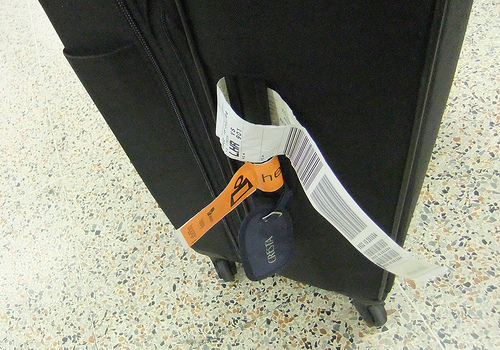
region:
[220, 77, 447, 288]
White tag on luggage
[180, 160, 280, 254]
Yellow tag on luggage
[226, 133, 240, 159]
Black letters on white tag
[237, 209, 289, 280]
Cloth tag on luggage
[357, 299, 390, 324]
Small wheel on luggage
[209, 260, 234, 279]
Small wheel on luggage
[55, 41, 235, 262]
Pocket on side of luggage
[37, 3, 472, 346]
Tall suitcase on floor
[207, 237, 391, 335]
black wheels on the luggage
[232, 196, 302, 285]
travel identification tag attached to the luggage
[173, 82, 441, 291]
travel tags attached to the luggage handle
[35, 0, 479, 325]
rolling black luggage sitting on a floor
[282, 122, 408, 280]
barcode for scanning on the tag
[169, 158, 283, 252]
orange tag attached to luggage handle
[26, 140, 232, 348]
multicolored flooring the luggage is on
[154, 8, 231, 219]
zipper area of the luggage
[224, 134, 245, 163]
code for the destination of travel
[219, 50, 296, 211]
handle of the luggage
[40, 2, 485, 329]
a suitcase is stand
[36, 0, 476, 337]
the suitcase is color black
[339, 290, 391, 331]
a wheel on right side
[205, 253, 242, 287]
a wheel on left side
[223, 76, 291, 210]
the handle of a suitcase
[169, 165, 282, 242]
an orange label attached to handle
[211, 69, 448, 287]
a white label on a handle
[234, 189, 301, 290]
a blue tag hangs from handle of suitcase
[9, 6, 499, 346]
suitcase is on floor of granite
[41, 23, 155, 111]
a pocket on side the suitcase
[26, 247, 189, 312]
the floor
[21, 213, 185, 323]
tile floor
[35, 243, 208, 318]
colorful floor under the suitcase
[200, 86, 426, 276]
a white tag on the suitcasd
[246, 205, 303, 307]
a black tag on the suitcase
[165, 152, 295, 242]
a yellow tag on the suitcase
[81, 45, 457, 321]
a black suitcase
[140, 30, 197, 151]
a zipper on the suitcase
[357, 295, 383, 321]
wheels on the suitcase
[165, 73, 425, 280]
tags on the handle of the suitcase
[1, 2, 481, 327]
luggage standing upright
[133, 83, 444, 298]
tags on the luggage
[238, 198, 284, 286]
identity luggage tag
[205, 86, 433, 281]
tags the indicate where the luggage is going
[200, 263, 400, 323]
wheels on the luggage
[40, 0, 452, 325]
black fabric luggage with wheels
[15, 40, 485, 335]
flooring in a building or airport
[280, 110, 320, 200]
barcode to scan luggage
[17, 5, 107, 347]
grout lines in the tiles on the floor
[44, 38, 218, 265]
bag has a front pocket